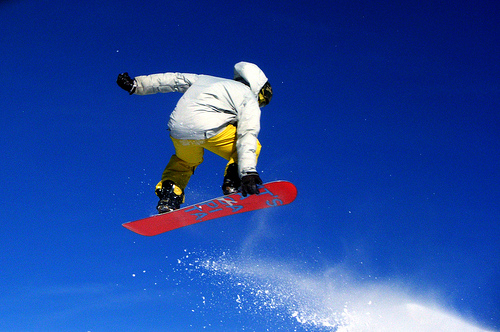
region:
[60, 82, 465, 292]
sky is clear and blue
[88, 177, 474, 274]
sky is clear and blue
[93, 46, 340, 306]
adult snow boarding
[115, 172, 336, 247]
red snow board with graphics on bottom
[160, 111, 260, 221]
bright yellow snow pants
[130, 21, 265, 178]
light gray snow jacket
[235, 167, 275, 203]
black snow gloves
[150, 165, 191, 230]
black snow boots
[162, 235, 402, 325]
white snow dust off snow board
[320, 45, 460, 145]
bright blue sky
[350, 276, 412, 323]
snow dust off snow board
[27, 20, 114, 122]
bright blue sky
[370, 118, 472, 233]
sky is clear and blue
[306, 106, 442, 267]
sky is clear and blue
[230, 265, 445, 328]
sky is clear and blue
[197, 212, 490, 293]
sky is clear and blue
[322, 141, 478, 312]
sky is clear and blue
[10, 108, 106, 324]
sky is clear and blue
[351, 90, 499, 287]
sky is clear and blue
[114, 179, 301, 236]
red and blue snowboard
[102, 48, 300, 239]
snowboarder in mid-jump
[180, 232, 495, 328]
snow dust flying in air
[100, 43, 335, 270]
snowboarder with back to camera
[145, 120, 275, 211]
yellow pants on snowboarder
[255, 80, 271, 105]
yellow goggles on snowboarder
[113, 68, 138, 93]
black gloves on snowboarder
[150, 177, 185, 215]
black boots on snowboarder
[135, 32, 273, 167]
silver hooded coat on snowboarder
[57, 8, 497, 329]
Snowboarder jumping over snow rift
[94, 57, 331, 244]
snowboarder in mid air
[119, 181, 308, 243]
red snowboard being used by man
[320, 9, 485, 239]
blue clear sky in the background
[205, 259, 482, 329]
white snow being lifted up by snowboard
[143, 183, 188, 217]
left snow boot of man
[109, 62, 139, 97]
left glove of snowboarder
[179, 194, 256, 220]
blue lettering on the snowboard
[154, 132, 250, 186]
yellow ski pants snowboarder is wearing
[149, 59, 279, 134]
grey snow jacket of snowboarder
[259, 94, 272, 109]
goggles of the snowboarder